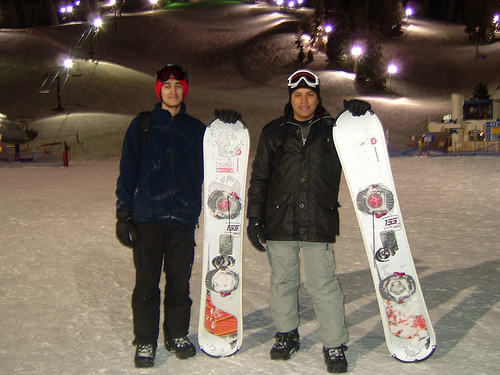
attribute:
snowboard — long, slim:
[205, 108, 251, 364]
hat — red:
[149, 70, 190, 87]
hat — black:
[287, 84, 324, 92]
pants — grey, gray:
[274, 237, 348, 347]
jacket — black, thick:
[249, 128, 343, 242]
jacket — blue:
[116, 120, 202, 222]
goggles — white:
[286, 75, 323, 90]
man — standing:
[244, 67, 355, 368]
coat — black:
[254, 130, 334, 224]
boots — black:
[132, 339, 196, 371]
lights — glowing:
[81, 16, 107, 27]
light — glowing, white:
[342, 43, 368, 61]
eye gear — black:
[154, 65, 189, 79]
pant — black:
[128, 231, 194, 340]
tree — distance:
[315, 5, 390, 87]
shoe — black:
[272, 327, 300, 365]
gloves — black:
[245, 216, 272, 255]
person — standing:
[120, 55, 204, 364]